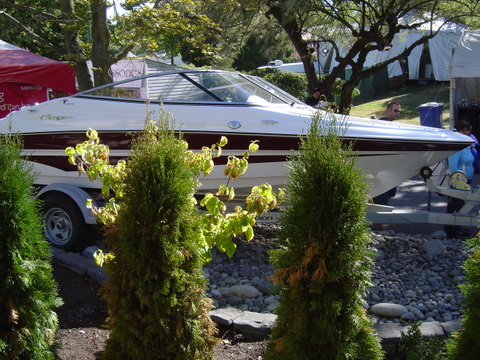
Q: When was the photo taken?
A: Afternoon.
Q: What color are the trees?
A: Green.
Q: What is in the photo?
A: A boat.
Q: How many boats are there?
A: One.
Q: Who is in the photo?
A: No one.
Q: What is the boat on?
A: Rocks.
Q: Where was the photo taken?
A: In a house.